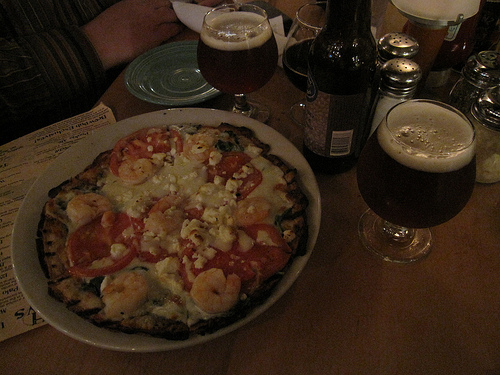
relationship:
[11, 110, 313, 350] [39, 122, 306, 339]
plate with a dinner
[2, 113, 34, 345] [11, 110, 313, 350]
paper under plate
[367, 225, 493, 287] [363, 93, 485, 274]
table under glass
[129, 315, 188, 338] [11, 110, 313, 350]
bread crust on plate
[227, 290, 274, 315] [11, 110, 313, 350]
bread crust on plate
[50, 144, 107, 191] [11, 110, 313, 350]
bread crust on plate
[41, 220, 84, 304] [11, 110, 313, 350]
bread crust on plate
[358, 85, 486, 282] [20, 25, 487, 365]
wine glass on table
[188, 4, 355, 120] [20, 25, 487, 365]
wine glass on table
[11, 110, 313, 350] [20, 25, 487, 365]
plate on table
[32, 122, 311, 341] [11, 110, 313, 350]
dinner on a plate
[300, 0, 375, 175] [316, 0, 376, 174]
bottle of liquid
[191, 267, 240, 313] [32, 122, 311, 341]
shrimp on a dinner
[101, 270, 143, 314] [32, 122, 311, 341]
shrimp on a dinner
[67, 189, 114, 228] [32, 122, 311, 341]
shrimp on a dinner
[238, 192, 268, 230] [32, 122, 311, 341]
shrimp on a dinner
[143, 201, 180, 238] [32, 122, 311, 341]
shrimp on a dinner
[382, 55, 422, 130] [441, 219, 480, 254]
salt shaker on table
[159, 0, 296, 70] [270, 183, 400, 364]
napkin on table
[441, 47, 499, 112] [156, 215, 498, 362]
shaker on table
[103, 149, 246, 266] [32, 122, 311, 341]
cheese on dinner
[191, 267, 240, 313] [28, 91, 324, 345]
shrimp on pizza